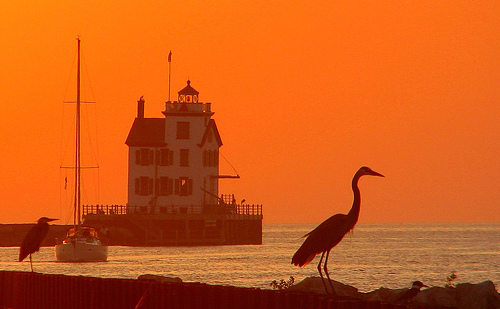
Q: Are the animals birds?
A: Yes, all the animals are birds.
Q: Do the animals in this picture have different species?
A: No, all the animals are birds.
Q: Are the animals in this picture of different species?
A: No, all the animals are birds.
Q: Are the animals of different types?
A: No, all the animals are birds.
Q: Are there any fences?
A: Yes, there is a fence.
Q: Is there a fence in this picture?
A: Yes, there is a fence.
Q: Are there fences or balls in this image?
A: Yes, there is a fence.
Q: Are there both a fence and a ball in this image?
A: No, there is a fence but no balls.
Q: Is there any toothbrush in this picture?
A: No, there are no toothbrushes.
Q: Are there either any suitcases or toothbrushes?
A: No, there are no toothbrushes or suitcases.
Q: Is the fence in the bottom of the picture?
A: Yes, the fence is in the bottom of the image.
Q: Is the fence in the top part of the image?
A: No, the fence is in the bottom of the image.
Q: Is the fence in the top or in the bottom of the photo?
A: The fence is in the bottom of the image.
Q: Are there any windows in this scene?
A: Yes, there are windows.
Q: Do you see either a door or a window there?
A: Yes, there are windows.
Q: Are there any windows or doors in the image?
A: Yes, there are windows.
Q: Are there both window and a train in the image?
A: No, there are windows but no trains.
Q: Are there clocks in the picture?
A: No, there are no clocks.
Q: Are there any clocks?
A: No, there are no clocks.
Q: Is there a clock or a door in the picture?
A: No, there are no clocks or doors.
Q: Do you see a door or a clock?
A: No, there are no clocks or doors.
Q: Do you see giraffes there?
A: No, there are no giraffes.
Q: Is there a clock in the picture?
A: No, there are no clocks.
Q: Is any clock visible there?
A: No, there are no clocks.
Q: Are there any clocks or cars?
A: No, there are no clocks or cars.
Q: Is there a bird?
A: Yes, there is a bird.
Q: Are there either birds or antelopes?
A: Yes, there is a bird.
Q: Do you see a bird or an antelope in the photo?
A: Yes, there is a bird.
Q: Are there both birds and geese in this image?
A: No, there is a bird but no geese.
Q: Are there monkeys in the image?
A: No, there are no monkeys.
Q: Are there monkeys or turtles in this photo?
A: No, there are no monkeys or turtles.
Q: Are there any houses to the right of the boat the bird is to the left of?
A: Yes, there is a house to the right of the boat.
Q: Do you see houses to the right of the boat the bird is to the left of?
A: Yes, there is a house to the right of the boat.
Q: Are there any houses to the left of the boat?
A: No, the house is to the right of the boat.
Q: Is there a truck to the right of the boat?
A: No, there is a house to the right of the boat.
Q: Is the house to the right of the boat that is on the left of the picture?
A: Yes, the house is to the right of the boat.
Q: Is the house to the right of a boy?
A: No, the house is to the right of the boat.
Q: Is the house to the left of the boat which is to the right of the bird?
A: No, the house is to the right of the boat.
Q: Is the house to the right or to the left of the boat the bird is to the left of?
A: The house is to the right of the boat.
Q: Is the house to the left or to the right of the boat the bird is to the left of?
A: The house is to the right of the boat.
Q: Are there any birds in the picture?
A: Yes, there is a bird.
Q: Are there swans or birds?
A: Yes, there is a bird.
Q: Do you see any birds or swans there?
A: Yes, there is a bird.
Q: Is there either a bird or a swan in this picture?
A: Yes, there is a bird.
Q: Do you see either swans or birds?
A: Yes, there is a bird.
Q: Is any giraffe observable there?
A: No, there are no giraffes.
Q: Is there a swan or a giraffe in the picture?
A: No, there are no giraffes or swans.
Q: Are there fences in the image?
A: Yes, there is a fence.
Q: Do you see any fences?
A: Yes, there is a fence.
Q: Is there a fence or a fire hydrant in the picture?
A: Yes, there is a fence.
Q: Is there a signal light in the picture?
A: No, there are no traffic lights.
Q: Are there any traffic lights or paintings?
A: No, there are no traffic lights or paintings.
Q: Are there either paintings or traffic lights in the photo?
A: No, there are no traffic lights or paintings.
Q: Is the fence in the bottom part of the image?
A: Yes, the fence is in the bottom of the image.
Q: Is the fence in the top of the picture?
A: No, the fence is in the bottom of the image.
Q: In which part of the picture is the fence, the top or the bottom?
A: The fence is in the bottom of the image.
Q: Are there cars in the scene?
A: No, there are no cars.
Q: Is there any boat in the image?
A: Yes, there is a boat.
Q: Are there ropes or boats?
A: Yes, there is a boat.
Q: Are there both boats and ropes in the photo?
A: No, there is a boat but no ropes.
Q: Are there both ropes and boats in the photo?
A: No, there is a boat but no ropes.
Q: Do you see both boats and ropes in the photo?
A: No, there is a boat but no ropes.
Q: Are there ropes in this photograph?
A: No, there are no ropes.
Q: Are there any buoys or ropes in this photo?
A: No, there are no ropes or buoys.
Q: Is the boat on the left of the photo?
A: Yes, the boat is on the left of the image.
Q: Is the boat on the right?
A: No, the boat is on the left of the image.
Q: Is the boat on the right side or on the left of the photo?
A: The boat is on the left of the image.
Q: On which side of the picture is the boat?
A: The boat is on the left of the image.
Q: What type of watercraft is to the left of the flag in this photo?
A: The watercraft is a boat.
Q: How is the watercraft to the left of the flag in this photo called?
A: The watercraft is a boat.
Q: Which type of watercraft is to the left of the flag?
A: The watercraft is a boat.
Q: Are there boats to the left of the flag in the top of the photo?
A: Yes, there is a boat to the left of the flag.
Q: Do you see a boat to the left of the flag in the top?
A: Yes, there is a boat to the left of the flag.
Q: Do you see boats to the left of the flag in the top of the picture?
A: Yes, there is a boat to the left of the flag.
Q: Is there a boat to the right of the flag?
A: No, the boat is to the left of the flag.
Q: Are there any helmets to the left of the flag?
A: No, there is a boat to the left of the flag.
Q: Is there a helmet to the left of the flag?
A: No, there is a boat to the left of the flag.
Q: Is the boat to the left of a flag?
A: Yes, the boat is to the left of a flag.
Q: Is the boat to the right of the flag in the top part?
A: No, the boat is to the left of the flag.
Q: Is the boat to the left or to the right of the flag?
A: The boat is to the left of the flag.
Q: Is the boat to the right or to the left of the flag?
A: The boat is to the left of the flag.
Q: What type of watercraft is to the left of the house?
A: The watercraft is a boat.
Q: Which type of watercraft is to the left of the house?
A: The watercraft is a boat.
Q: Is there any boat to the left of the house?
A: Yes, there is a boat to the left of the house.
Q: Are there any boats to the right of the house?
A: No, the boat is to the left of the house.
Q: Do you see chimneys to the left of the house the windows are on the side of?
A: No, there is a boat to the left of the house.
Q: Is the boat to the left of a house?
A: Yes, the boat is to the left of a house.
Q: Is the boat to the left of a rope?
A: No, the boat is to the left of a house.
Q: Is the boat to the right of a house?
A: No, the boat is to the left of a house.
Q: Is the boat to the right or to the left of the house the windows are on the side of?
A: The boat is to the left of the house.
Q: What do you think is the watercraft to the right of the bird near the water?
A: The watercraft is a boat.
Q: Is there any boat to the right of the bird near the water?
A: Yes, there is a boat to the right of the bird.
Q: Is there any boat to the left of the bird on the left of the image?
A: No, the boat is to the right of the bird.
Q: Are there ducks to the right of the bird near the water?
A: No, there is a boat to the right of the bird.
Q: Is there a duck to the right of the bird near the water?
A: No, there is a boat to the right of the bird.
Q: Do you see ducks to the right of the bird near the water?
A: No, there is a boat to the right of the bird.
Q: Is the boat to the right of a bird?
A: Yes, the boat is to the right of a bird.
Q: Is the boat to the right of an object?
A: No, the boat is to the right of a bird.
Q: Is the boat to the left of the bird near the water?
A: No, the boat is to the right of the bird.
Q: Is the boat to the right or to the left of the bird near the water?
A: The boat is to the right of the bird.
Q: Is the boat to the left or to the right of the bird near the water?
A: The boat is to the right of the bird.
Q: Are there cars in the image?
A: No, there are no cars.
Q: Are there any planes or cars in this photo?
A: No, there are no cars or planes.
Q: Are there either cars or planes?
A: No, there are no cars or planes.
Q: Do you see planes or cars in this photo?
A: No, there are no cars or planes.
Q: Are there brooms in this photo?
A: No, there are no brooms.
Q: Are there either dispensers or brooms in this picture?
A: No, there are no brooms or dispensers.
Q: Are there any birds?
A: Yes, there is a bird.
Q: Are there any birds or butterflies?
A: Yes, there is a bird.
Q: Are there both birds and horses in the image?
A: No, there is a bird but no horses.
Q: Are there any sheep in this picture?
A: No, there are no sheep.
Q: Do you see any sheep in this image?
A: No, there are no sheep.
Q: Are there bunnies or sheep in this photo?
A: No, there are no sheep or bunnies.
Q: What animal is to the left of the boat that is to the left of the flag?
A: The animal is a bird.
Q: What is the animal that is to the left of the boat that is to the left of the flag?
A: The animal is a bird.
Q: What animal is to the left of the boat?
A: The animal is a bird.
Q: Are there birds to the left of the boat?
A: Yes, there is a bird to the left of the boat.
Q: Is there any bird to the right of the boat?
A: No, the bird is to the left of the boat.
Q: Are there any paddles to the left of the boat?
A: No, there is a bird to the left of the boat.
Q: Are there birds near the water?
A: Yes, there is a bird near the water.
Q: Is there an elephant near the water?
A: No, there is a bird near the water.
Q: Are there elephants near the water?
A: No, there is a bird near the water.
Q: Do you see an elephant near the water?
A: No, there is a bird near the water.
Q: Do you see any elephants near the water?
A: No, there is a bird near the water.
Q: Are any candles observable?
A: No, there are no candles.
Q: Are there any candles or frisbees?
A: No, there are no candles or frisbees.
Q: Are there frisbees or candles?
A: No, there are no candles or frisbees.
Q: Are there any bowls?
A: No, there are no bowls.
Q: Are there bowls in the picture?
A: No, there are no bowls.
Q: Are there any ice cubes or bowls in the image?
A: No, there are no bowls or ice cubes.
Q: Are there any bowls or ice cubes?
A: No, there are no bowls or ice cubes.